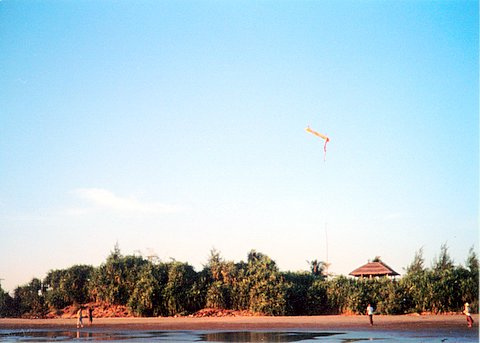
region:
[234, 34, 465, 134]
The sky is clear.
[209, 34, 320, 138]
The sky is clear.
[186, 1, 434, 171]
The sky is clear.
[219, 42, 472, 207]
The sky is clear.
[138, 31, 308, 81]
The sky is clear.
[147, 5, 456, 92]
The sky is clear.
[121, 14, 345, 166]
The sky is clear.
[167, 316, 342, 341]
reflections of trees in the water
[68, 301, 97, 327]
two people by the water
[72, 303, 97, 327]
two people walking by the shore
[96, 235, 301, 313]
trees with green leaves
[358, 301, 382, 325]
person in white shirt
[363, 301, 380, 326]
person in white shirt standing by shore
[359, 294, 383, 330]
person in black pants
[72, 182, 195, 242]
wispy white cloud in sky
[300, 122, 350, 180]
red kite in sky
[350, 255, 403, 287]
building with red roof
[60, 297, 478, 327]
people are on the beach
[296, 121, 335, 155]
kite is in the air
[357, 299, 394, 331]
person has white shirt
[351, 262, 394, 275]
the roof is red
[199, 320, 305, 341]
the water is on the beach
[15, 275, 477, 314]
the trees are grouped together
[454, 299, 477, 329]
the person is female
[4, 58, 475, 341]
the scene is outdoors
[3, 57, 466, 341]
the day is very clear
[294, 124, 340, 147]
the kite is very high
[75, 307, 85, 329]
a person walking along the beach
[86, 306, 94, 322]
a person walking along the beach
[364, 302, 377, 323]
a person walking along the beach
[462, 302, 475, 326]
a person walking along the beach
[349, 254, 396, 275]
the brown roof of a hut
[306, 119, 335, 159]
a long yellow orange kit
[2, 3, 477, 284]
the light blue sky above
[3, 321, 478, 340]
a body of dark colored water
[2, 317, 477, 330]
the sandy beach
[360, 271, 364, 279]
the pole of a hut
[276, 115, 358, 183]
kite flying through the air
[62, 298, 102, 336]
people watching a kite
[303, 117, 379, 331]
person flying a kite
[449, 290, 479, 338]
person watching a kite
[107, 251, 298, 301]
green forest near the water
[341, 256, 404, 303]
gazebo in the forest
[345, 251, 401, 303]
gazebo near the water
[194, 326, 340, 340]
reflection of trees in the water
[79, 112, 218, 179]
clear and cloudless blue sky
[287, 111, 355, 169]
yellow and pink kite with a tail